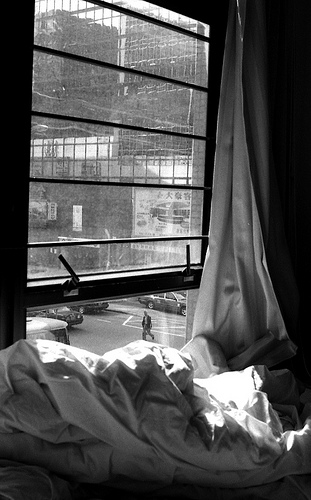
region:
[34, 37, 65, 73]
white pane in the window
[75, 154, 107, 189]
white pane in the window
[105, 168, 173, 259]
white pane in the window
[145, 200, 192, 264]
white pane in the window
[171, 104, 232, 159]
white pane in the window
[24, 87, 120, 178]
white pane in the window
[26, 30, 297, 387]
an opened window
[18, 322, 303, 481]
a wadded up blanket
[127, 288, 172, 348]
a person crossing the street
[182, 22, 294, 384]
a curtain pushed to the side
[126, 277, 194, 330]
a car in the road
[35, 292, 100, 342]
a car driving in the road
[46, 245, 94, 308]
a window lock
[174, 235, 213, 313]
a window lock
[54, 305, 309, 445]
sun shining on a blanket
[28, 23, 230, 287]
window with many pains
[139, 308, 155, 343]
man walking in the street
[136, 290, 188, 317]
car parked on the street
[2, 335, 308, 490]
a crumpled up blanket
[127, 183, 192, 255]
a bill board with asian writing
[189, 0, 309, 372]
a curtain on a window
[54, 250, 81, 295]
a window handle pointed up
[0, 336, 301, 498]
a white blanket with wrinkles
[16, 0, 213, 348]
a window open to the street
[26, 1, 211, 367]
a view out of a window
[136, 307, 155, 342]
a man in a dark coat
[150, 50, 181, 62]
the view of a white wall and chairs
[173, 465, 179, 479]
the view of a white wall and chairs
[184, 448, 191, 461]
the view of a white wall and chairs